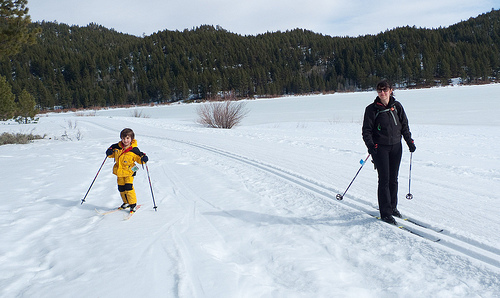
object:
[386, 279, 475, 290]
snow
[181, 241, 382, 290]
snow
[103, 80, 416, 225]
people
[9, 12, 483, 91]
trees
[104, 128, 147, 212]
boy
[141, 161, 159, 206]
pole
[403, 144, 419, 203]
pole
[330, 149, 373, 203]
pole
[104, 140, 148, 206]
coat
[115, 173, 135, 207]
pants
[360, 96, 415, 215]
coat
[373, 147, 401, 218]
pants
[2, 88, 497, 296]
field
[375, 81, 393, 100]
head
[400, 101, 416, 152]
arm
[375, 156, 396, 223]
leg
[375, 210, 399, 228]
feet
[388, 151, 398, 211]
leg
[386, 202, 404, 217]
feet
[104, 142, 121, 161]
arm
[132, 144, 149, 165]
arm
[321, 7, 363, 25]
clouds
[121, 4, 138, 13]
clouds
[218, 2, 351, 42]
clouds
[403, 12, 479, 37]
clouds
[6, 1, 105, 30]
sky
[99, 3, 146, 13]
clouds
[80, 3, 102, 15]
clouds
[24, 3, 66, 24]
clouds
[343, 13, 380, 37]
clouds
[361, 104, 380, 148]
arm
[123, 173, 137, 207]
leg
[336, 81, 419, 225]
person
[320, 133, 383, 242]
ski